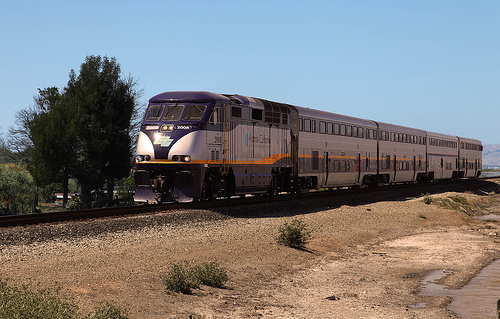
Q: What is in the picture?
A: A train.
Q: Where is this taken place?
A: By railroad tracks.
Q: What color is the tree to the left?
A: Green.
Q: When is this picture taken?
A: In the Daytime.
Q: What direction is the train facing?
A: Left.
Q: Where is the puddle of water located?
A: On the bottom right.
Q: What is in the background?
A: Trees and shrubs.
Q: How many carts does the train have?
A: 4.